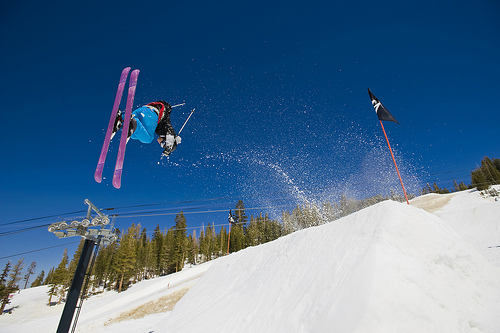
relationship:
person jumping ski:
[111, 98, 182, 158] [112, 68, 139, 188]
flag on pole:
[366, 87, 400, 127] [377, 117, 411, 202]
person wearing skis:
[111, 99, 182, 156] [79, 63, 160, 185]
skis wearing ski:
[79, 63, 160, 185] [112, 63, 129, 187]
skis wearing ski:
[79, 63, 160, 185] [95, 50, 111, 190]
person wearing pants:
[111, 99, 182, 156] [122, 102, 159, 147]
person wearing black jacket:
[111, 99, 182, 156] [156, 100, 178, 143]